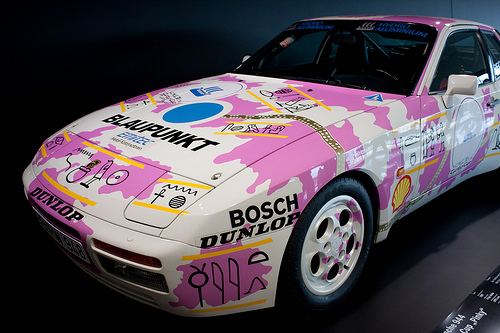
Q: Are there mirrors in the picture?
A: Yes, there is a mirror.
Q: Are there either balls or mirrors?
A: Yes, there is a mirror.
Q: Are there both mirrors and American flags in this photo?
A: No, there is a mirror but no American flags.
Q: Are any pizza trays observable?
A: No, there are no pizza trays.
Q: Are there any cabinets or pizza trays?
A: No, there are no pizza trays or cabinets.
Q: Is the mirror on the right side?
A: Yes, the mirror is on the right of the image.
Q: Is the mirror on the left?
A: No, the mirror is on the right of the image.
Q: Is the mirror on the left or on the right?
A: The mirror is on the right of the image.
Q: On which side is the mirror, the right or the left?
A: The mirror is on the right of the image.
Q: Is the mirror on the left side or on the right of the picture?
A: The mirror is on the right of the image.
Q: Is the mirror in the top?
A: Yes, the mirror is in the top of the image.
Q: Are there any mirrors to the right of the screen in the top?
A: Yes, there is a mirror to the right of the screen.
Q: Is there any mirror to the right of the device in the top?
A: Yes, there is a mirror to the right of the screen.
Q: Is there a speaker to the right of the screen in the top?
A: No, there is a mirror to the right of the screen.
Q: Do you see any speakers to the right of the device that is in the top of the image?
A: No, there is a mirror to the right of the screen.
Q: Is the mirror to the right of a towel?
A: No, the mirror is to the right of the screen.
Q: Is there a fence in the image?
A: No, there are no fences.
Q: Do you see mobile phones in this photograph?
A: No, there are no mobile phones.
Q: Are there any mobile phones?
A: No, there are no mobile phones.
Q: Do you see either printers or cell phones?
A: No, there are no cell phones or printers.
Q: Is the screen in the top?
A: Yes, the screen is in the top of the image.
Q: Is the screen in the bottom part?
A: No, the screen is in the top of the image.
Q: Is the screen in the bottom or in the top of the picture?
A: The screen is in the top of the image.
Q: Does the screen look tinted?
A: Yes, the screen is tinted.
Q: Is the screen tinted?
A: Yes, the screen is tinted.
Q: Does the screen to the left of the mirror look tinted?
A: Yes, the screen is tinted.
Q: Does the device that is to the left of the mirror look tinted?
A: Yes, the screen is tinted.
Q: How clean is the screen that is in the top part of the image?
A: The screen is tinted.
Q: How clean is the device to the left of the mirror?
A: The screen is tinted.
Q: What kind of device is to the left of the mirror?
A: The device is a screen.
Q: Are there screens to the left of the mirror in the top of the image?
A: Yes, there is a screen to the left of the mirror.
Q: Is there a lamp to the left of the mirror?
A: No, there is a screen to the left of the mirror.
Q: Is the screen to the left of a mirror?
A: Yes, the screen is to the left of a mirror.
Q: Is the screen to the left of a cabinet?
A: No, the screen is to the left of a mirror.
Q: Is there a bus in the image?
A: No, there are no buses.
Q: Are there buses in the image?
A: No, there are no buses.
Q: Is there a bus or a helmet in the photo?
A: No, there are no buses or helmets.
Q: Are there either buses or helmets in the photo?
A: No, there are no buses or helmets.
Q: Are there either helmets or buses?
A: No, there are no buses or helmets.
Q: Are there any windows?
A: Yes, there is a window.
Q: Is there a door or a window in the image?
A: Yes, there is a window.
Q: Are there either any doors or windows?
A: Yes, there is a window.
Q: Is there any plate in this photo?
A: Yes, there is a plate.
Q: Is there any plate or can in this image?
A: Yes, there is a plate.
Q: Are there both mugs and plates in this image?
A: No, there is a plate but no mugs.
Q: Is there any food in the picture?
A: No, there is no food.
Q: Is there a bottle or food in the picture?
A: No, there are no food or bottles.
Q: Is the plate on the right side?
A: No, the plate is on the left of the image.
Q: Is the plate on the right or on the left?
A: The plate is on the left of the image.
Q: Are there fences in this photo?
A: No, there are no fences.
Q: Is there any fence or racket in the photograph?
A: No, there are no fences or rackets.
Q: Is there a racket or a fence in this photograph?
A: No, there are no fences or rackets.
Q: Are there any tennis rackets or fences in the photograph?
A: No, there are no fences or tennis rackets.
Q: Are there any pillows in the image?
A: No, there are no pillows.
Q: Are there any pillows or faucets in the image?
A: No, there are no pillows or faucets.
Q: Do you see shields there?
A: No, there are no shields.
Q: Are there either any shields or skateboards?
A: No, there are no shields or skateboards.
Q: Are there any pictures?
A: No, there are no pictures.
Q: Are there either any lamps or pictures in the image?
A: No, there are no pictures or lamps.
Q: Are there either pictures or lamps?
A: No, there are no pictures or lamps.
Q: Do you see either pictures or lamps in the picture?
A: No, there are no pictures or lamps.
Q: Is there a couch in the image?
A: No, there are no couches.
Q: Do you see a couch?
A: No, there are no couches.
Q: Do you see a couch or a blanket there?
A: No, there are no couches or blankets.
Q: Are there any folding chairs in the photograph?
A: No, there are no folding chairs.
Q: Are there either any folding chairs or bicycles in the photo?
A: No, there are no folding chairs or bicycles.